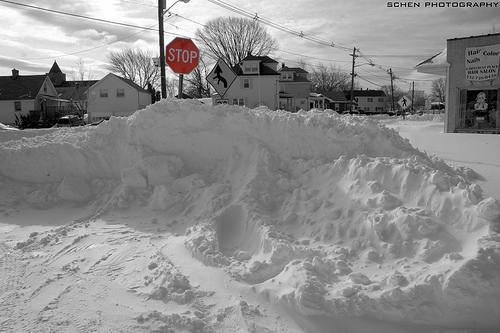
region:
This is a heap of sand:
[396, 230, 477, 302]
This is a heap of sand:
[250, 194, 378, 279]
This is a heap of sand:
[220, 162, 347, 247]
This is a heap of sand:
[177, 133, 329, 244]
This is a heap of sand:
[163, 170, 295, 249]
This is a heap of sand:
[99, 108, 242, 192]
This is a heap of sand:
[293, 176, 430, 283]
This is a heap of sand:
[110, 74, 351, 266]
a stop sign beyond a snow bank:
[107, 3, 253, 268]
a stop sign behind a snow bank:
[127, 2, 242, 307]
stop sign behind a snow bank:
[127, 2, 274, 309]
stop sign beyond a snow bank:
[111, 5, 253, 292]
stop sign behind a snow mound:
[125, 6, 275, 250]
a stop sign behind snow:
[107, 5, 271, 304]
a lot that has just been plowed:
[21, 13, 497, 277]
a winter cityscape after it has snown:
[21, 5, 496, 241]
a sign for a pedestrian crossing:
[383, 76, 420, 133]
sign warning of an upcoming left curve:
[201, 50, 250, 107]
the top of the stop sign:
[164, 32, 197, 72]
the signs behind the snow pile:
[161, 34, 236, 103]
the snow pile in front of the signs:
[31, 98, 418, 280]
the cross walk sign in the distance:
[395, 93, 412, 118]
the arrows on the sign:
[214, 61, 230, 89]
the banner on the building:
[458, 45, 496, 81]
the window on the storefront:
[458, 85, 498, 131]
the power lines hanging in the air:
[198, 0, 352, 66]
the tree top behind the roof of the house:
[199, 15, 276, 54]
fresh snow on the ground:
[1, 103, 496, 328]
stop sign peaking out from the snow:
[162, 34, 197, 99]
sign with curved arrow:
[207, 56, 236, 96]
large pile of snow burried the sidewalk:
[0, 96, 496, 328]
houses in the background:
[1, 31, 498, 128]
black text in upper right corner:
[377, 2, 499, 14]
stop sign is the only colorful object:
[164, 34, 201, 101]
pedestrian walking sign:
[397, 91, 411, 114]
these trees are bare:
[112, 14, 279, 84]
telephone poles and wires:
[5, 0, 415, 111]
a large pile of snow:
[0, 100, 492, 330]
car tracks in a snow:
[11, 201, 226, 327]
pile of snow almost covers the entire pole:
[2, 96, 413, 199]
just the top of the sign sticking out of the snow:
[160, 31, 202, 94]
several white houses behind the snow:
[0, 46, 397, 116]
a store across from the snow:
[411, 28, 494, 138]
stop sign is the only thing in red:
[161, 31, 197, 77]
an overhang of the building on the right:
[418, 41, 448, 76]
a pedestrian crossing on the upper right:
[388, 87, 413, 118]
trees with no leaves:
[106, 17, 276, 104]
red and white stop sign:
[160, 30, 204, 99]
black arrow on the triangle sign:
[200, 53, 241, 103]